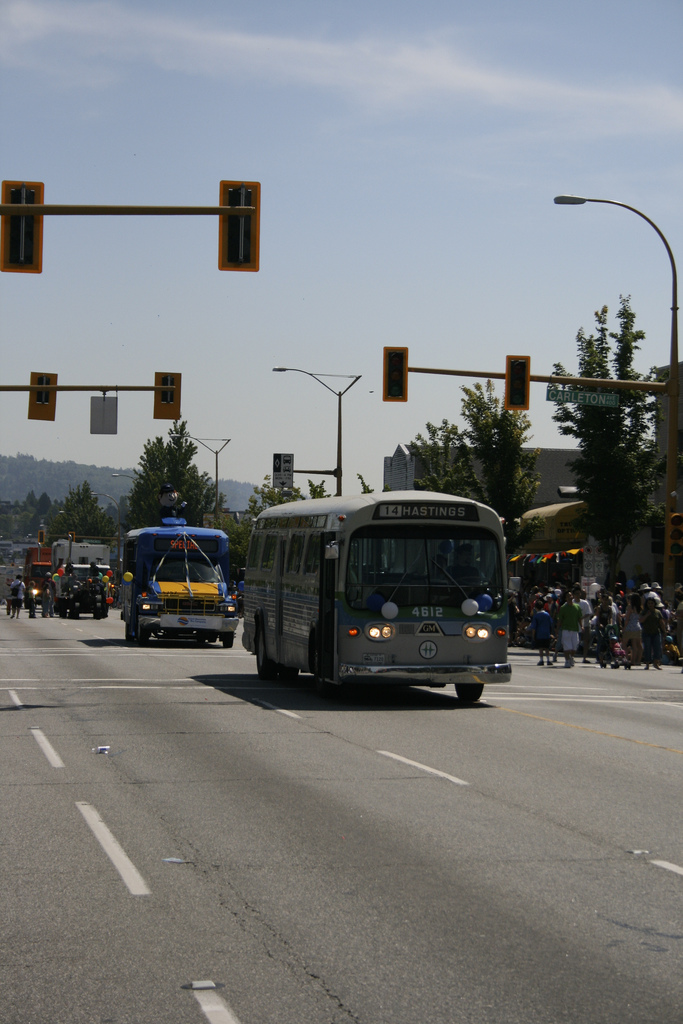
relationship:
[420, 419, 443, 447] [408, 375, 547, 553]
leaves on tree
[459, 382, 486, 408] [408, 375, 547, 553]
leaves on tree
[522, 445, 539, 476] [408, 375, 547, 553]
leaves on tree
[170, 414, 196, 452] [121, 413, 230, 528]
leaves on tree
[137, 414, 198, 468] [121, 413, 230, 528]
leaves on tree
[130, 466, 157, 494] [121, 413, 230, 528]
leaves on tree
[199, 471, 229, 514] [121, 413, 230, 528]
leaves on tree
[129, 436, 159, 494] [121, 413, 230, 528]
leaves on tree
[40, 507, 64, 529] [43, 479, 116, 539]
leaves on tree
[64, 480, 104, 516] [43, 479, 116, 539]
leaves on tree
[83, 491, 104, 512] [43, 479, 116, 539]
leaves on tree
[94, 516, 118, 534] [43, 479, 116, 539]
leaves on tree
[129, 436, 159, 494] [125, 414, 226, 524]
leaves on tree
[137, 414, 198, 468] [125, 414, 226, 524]
leaves on tree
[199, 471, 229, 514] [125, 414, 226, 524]
leaves on tree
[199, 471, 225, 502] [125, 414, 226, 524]
leaves on tree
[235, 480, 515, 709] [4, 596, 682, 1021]
bus on road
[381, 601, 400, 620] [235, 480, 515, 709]
ballon on bus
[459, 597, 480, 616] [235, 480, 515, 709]
ballon on bus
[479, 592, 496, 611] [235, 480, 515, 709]
ballon on bus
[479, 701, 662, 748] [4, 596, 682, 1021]
line painted on road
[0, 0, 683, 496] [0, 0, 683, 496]
cloud hanging in cloud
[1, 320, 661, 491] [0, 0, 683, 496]
cloud hanging in cloud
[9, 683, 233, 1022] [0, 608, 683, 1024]
lines on road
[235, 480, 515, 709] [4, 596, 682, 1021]
bus going down road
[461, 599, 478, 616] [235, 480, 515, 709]
ballon on front of bus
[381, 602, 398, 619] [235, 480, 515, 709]
ballon on front of bus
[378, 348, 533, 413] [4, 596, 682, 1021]
lights above road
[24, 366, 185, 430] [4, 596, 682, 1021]
lights above road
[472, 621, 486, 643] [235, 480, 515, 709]
head light on bus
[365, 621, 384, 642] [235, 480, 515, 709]
head light on bus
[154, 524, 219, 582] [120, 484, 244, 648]
streamer on front of bus